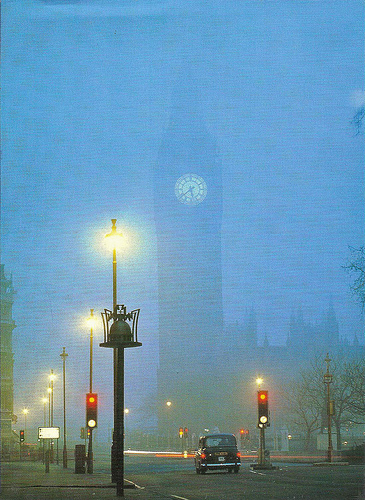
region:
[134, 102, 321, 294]
Clock on the tower.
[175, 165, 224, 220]
Lit up clock on the tower.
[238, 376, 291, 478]
Light on the pole.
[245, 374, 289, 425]
Red light on the pole.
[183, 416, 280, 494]
Car on the road.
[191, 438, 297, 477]
Tail lights on the car.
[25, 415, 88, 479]
Sign on the street.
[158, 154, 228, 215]
Hands on the clock.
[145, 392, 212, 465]
Lights in the distance.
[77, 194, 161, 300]
Light on the lamp pole.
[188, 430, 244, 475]
Black car on road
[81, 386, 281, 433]
Traffic lights on poles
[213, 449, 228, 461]
License plate of car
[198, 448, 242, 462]
Tail lights of car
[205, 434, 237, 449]
Rear window of car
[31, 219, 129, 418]
Street lights on light poles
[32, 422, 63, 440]
White traffic sign on pole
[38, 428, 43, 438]
black arrows on white traffic sign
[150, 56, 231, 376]
Clock tower in distance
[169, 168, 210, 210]
Clock on clock tower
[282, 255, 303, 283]
part of the sky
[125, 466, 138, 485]
edge of a road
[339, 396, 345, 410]
part of a branch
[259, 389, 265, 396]
part of a light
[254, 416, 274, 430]
part of a light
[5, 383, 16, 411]
part of a building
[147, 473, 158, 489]
side of a road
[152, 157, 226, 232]
A Clock on a building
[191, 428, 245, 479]
A car on a street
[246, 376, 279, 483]
The stoplight is red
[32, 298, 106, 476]
Street lights in the city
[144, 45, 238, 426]
A tall building in the fog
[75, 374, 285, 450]
Two red stop lights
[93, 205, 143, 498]
A lighted street light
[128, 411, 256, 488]
A car driving down the street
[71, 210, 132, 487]
Two street lights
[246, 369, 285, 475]
A street light and stoplight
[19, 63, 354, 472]
foggy evening in the city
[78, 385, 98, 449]
red traffic light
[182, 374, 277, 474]
automobile stopped at a light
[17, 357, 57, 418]
group of street lights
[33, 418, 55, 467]
information sign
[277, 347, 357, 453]
trees along the city street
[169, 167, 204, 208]
clock face says 5:38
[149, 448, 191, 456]
red caution line on the curb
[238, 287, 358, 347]
silhouette of building tops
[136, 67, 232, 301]
shrouded clock tower